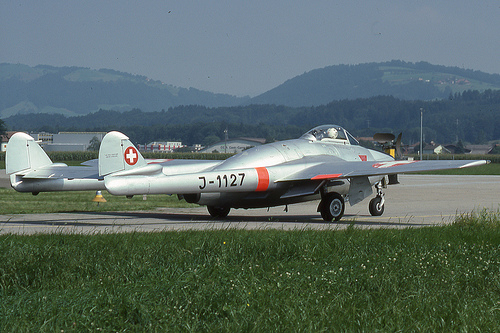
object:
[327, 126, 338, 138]
pilot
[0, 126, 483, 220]
plane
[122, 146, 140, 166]
circle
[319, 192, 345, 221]
wheel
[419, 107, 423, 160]
pole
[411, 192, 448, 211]
runway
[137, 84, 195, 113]
mountains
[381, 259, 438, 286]
grass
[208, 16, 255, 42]
sky